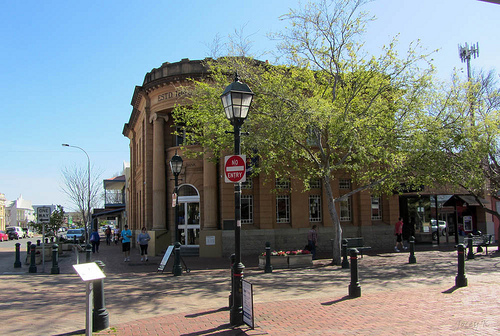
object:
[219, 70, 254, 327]
street lamp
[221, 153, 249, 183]
sign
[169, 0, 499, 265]
tree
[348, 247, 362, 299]
post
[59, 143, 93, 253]
lightpost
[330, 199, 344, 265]
trunk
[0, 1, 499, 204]
sky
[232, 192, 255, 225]
window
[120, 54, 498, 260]
building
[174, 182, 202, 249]
door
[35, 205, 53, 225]
sign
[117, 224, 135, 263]
man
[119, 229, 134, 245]
shirt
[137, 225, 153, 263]
people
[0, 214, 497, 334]
sidewalk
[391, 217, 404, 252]
man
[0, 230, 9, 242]
car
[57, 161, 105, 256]
tree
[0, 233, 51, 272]
street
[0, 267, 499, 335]
pavement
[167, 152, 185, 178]
light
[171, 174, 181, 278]
pole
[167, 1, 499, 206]
leaves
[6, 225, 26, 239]
cars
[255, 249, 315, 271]
planter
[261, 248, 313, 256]
flowers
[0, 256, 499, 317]
shadow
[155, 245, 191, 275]
street sign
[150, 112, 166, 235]
column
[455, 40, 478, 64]
cellphone tower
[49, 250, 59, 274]
posts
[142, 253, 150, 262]
sneakers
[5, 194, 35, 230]
building